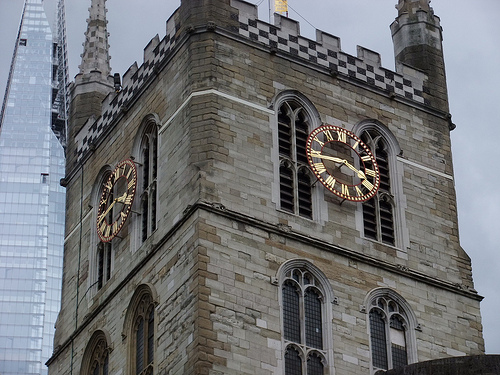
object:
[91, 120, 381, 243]
clock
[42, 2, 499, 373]
building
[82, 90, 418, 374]
windows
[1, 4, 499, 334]
sky